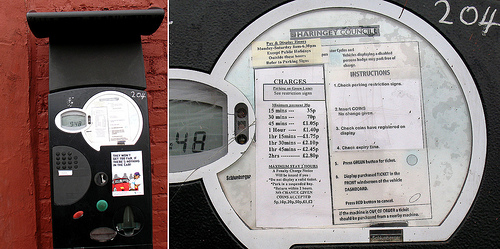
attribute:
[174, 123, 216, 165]
number — hand written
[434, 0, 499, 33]
number 204 — written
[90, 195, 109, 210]
button — green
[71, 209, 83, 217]
button — red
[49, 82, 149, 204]
town meter — pre-paid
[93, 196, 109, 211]
button — rubber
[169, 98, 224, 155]
screen — led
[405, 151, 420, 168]
circle — black, white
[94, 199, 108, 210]
button — green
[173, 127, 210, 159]
number — digital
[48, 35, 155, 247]
box — black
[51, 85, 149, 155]
circle — round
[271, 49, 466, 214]
instructions — black, written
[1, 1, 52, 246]
brick wall — red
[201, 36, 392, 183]
scale — black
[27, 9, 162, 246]
machine — black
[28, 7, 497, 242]
meter — black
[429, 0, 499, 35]
handwritten numbers — white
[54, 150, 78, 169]
buttons — small, black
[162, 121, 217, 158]
digital numbers — black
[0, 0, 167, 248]
wall — brick, painted, red